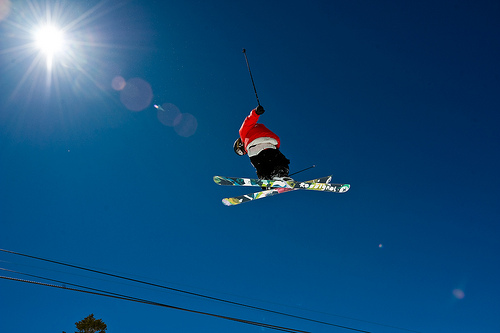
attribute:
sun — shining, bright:
[1, 2, 146, 122]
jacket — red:
[238, 108, 281, 153]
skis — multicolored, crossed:
[212, 174, 351, 207]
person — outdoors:
[232, 107, 295, 191]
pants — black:
[250, 148, 290, 192]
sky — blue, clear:
[0, 0, 498, 332]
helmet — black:
[232, 136, 246, 157]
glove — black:
[254, 104, 265, 117]